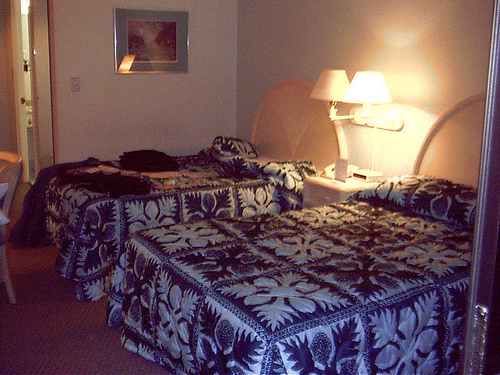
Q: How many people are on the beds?
A: Zero.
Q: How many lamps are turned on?
A: One.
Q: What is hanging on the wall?
A: Picture.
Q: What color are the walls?
A: White.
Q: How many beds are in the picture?
A: Two.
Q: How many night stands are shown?
A: One.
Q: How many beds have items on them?
A: One.